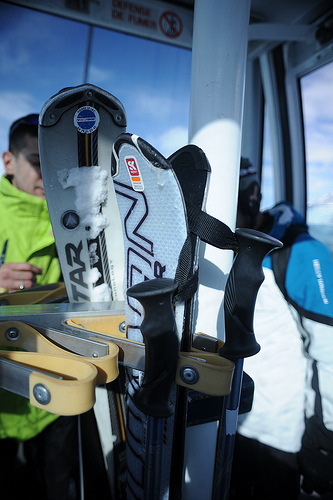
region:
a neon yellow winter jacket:
[0, 178, 66, 435]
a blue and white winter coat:
[225, 203, 329, 466]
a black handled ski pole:
[124, 277, 181, 498]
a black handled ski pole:
[214, 225, 282, 499]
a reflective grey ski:
[106, 132, 184, 498]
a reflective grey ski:
[43, 83, 136, 482]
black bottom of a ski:
[169, 140, 211, 350]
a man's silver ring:
[18, 280, 23, 288]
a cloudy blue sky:
[1, 6, 189, 169]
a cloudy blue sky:
[297, 63, 332, 252]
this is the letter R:
[55, 234, 92, 271]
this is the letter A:
[63, 258, 96, 295]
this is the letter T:
[54, 269, 100, 308]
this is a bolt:
[30, 380, 59, 409]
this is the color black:
[58, 446, 64, 451]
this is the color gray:
[190, 462, 200, 470]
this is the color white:
[253, 416, 265, 426]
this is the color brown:
[65, 394, 69, 398]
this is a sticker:
[122, 152, 149, 202]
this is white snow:
[55, 161, 116, 239]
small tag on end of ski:
[68, 104, 100, 135]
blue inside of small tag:
[80, 110, 95, 127]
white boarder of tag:
[69, 101, 104, 133]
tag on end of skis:
[122, 155, 143, 194]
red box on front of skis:
[124, 158, 140, 178]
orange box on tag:
[128, 175, 140, 182]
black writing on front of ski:
[108, 175, 173, 326]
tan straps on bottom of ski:
[0, 346, 113, 415]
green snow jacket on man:
[0, 186, 45, 276]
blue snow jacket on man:
[292, 236, 331, 313]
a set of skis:
[21, 78, 264, 497]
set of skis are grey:
[43, 77, 206, 498]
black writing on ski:
[91, 161, 176, 483]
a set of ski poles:
[112, 188, 266, 497]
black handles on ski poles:
[99, 216, 290, 411]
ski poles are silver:
[132, 334, 268, 498]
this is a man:
[2, 100, 101, 496]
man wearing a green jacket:
[0, 168, 120, 453]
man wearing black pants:
[0, 414, 101, 495]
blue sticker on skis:
[63, 100, 101, 132]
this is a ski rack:
[2, 298, 248, 498]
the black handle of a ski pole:
[124, 271, 193, 423]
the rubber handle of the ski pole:
[220, 217, 288, 363]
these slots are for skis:
[4, 317, 121, 419]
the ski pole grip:
[117, 266, 187, 425]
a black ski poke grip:
[214, 218, 275, 359]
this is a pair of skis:
[104, 120, 208, 497]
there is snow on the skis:
[61, 155, 119, 306]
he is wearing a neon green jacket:
[0, 111, 68, 289]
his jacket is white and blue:
[221, 149, 331, 449]